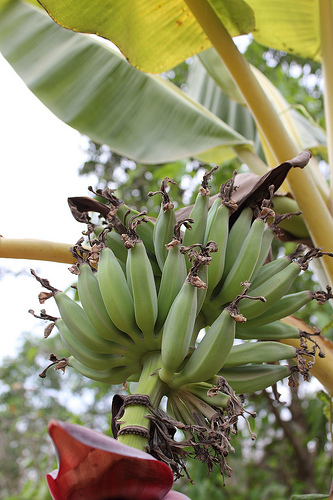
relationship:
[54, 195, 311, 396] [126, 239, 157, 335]
banana next to banana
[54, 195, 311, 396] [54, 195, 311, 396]
banana next to banana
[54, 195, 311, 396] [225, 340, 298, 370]
banana next to banana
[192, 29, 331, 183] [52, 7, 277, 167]
branches with leaves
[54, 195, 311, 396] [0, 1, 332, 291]
banana on tree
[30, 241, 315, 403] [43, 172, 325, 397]
cluster of bananas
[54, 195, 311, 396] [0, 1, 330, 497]
banana on tree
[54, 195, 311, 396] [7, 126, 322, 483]
banana hanging on tree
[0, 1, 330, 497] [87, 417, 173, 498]
tree at bottom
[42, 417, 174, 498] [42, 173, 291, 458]
leaf of plant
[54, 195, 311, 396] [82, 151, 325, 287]
banana with buntips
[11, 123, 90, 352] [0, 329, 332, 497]
sky in back of plant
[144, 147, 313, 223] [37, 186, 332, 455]
dried leaf on top of bananas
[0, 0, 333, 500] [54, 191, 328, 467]
tree behind bunches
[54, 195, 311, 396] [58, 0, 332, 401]
banana on tree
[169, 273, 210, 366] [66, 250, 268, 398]
banana on tree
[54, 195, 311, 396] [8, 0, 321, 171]
banana on tree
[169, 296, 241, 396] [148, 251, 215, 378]
fruit growing fruit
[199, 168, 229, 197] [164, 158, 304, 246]
objects at end of fruit